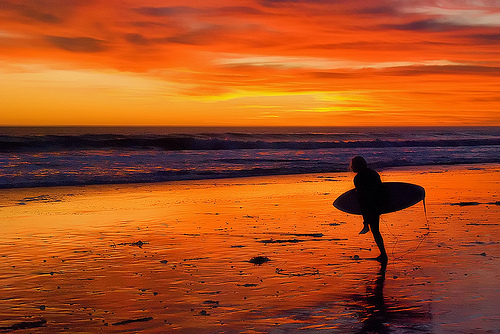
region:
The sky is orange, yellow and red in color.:
[22, 12, 401, 330]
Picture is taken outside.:
[27, 24, 412, 281]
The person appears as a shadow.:
[324, 152, 411, 315]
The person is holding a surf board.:
[314, 172, 446, 256]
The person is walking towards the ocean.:
[54, 116, 433, 204]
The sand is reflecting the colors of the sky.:
[104, 195, 319, 291]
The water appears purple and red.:
[60, 126, 406, 166]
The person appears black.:
[314, 135, 466, 292]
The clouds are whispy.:
[69, 8, 443, 58]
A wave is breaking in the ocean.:
[43, 115, 282, 158]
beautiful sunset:
[18, 6, 475, 162]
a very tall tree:
[20, 5, 492, 327]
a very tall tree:
[1, 70, 498, 206]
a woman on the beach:
[301, 152, 432, 277]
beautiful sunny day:
[6, 10, 475, 238]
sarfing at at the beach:
[326, 143, 428, 308]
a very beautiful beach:
[2, 160, 497, 331]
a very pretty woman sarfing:
[325, 145, 440, 285]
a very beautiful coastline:
[2, 127, 491, 232]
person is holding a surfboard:
[313, 141, 445, 283]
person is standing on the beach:
[321, 144, 443, 297]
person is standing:
[311, 145, 446, 260]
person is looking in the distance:
[307, 145, 457, 268]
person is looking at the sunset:
[306, 140, 446, 279]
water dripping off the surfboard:
[414, 181, 448, 233]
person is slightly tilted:
[324, 144, 471, 264]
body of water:
[3, 117, 493, 195]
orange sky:
[1, 3, 498, 142]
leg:
[362, 216, 404, 263]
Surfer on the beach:
[308, 136, 486, 286]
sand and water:
[137, 137, 299, 281]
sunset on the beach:
[79, 49, 246, 200]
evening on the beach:
[111, 62, 277, 226]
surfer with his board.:
[343, 80, 436, 302]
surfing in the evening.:
[286, 90, 486, 272]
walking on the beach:
[316, 106, 478, 330]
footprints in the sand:
[126, 233, 246, 328]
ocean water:
[121, 117, 249, 184]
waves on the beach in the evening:
[44, 141, 245, 283]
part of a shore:
[208, 198, 308, 265]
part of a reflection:
[203, 237, 260, 301]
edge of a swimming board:
[323, 194, 342, 213]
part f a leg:
[368, 240, 389, 268]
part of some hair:
[347, 153, 364, 170]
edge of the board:
[383, 190, 412, 215]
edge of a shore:
[114, 170, 186, 225]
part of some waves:
[123, 127, 173, 170]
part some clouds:
[271, 58, 333, 110]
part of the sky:
[111, 99, 157, 129]